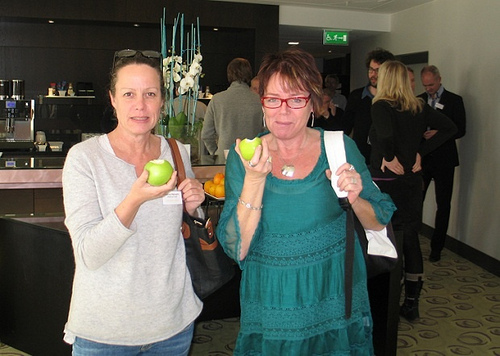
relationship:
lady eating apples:
[61, 48, 220, 355] [142, 144, 263, 173]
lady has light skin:
[100, 48, 169, 149] [129, 70, 146, 84]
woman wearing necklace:
[245, 46, 344, 208] [277, 151, 308, 180]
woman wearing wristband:
[245, 46, 344, 208] [239, 195, 263, 213]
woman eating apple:
[245, 46, 344, 208] [238, 138, 264, 157]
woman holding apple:
[245, 46, 344, 208] [238, 138, 264, 157]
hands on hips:
[383, 150, 422, 172] [405, 165, 414, 179]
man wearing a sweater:
[208, 53, 258, 123] [218, 97, 260, 120]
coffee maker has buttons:
[30, 84, 91, 139] [70, 96, 96, 106]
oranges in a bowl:
[202, 172, 223, 190] [204, 195, 223, 208]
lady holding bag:
[61, 48, 220, 355] [166, 135, 240, 297]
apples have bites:
[142, 144, 263, 173] [153, 157, 163, 165]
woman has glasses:
[245, 46, 344, 208] [262, 90, 309, 112]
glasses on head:
[262, 90, 309, 112] [257, 54, 319, 132]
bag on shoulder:
[198, 239, 222, 281] [165, 138, 184, 156]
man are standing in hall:
[411, 59, 466, 264] [325, 56, 359, 77]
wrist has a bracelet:
[243, 184, 261, 196] [241, 201, 257, 212]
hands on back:
[383, 150, 422, 172] [396, 138, 416, 153]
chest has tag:
[124, 157, 149, 174] [166, 193, 180, 207]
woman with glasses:
[245, 46, 344, 208] [262, 90, 309, 112]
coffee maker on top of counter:
[30, 84, 91, 139] [12, 158, 57, 174]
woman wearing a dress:
[245, 46, 344, 208] [265, 199, 335, 338]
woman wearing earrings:
[245, 46, 344, 208] [308, 110, 320, 133]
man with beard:
[364, 46, 382, 95] [370, 78, 376, 87]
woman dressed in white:
[245, 46, 344, 208] [103, 164, 115, 201]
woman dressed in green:
[245, 46, 344, 208] [276, 200, 298, 222]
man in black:
[208, 53, 258, 123] [450, 98, 458, 114]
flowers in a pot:
[161, 50, 203, 96] [164, 123, 206, 143]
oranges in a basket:
[202, 172, 223, 190] [204, 203, 216, 218]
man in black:
[417, 59, 456, 114] [450, 98, 458, 114]